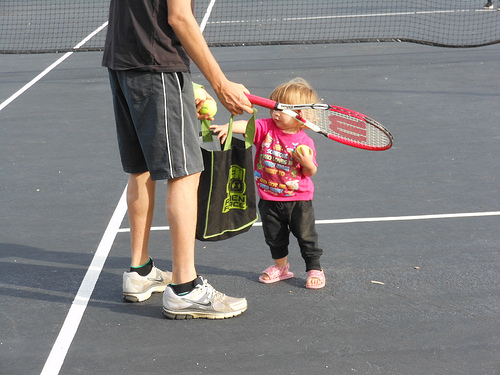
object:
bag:
[196, 108, 259, 242]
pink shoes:
[306, 269, 326, 289]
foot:
[162, 275, 247, 319]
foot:
[123, 259, 173, 302]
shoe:
[162, 275, 248, 319]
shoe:
[122, 256, 172, 303]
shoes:
[259, 262, 294, 283]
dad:
[101, 0, 253, 320]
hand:
[195, 97, 214, 121]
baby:
[210, 83, 326, 289]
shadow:
[0, 262, 171, 320]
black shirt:
[102, 0, 190, 73]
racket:
[244, 92, 394, 151]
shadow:
[0, 244, 307, 287]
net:
[0, 0, 500, 55]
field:
[0, 0, 500, 375]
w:
[328, 115, 366, 142]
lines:
[205, 9, 500, 25]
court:
[0, 0, 500, 375]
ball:
[199, 100, 217, 118]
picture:
[0, 0, 500, 375]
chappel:
[259, 262, 294, 283]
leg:
[259, 208, 290, 264]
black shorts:
[108, 67, 205, 181]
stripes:
[161, 72, 174, 179]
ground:
[6, 5, 496, 371]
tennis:
[294, 145, 313, 158]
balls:
[193, 88, 207, 100]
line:
[116, 210, 500, 233]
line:
[38, 0, 214, 375]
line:
[0, 20, 110, 111]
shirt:
[243, 118, 319, 202]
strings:
[301, 108, 390, 148]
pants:
[258, 198, 324, 273]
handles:
[223, 108, 258, 152]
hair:
[270, 77, 321, 129]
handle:
[243, 93, 277, 111]